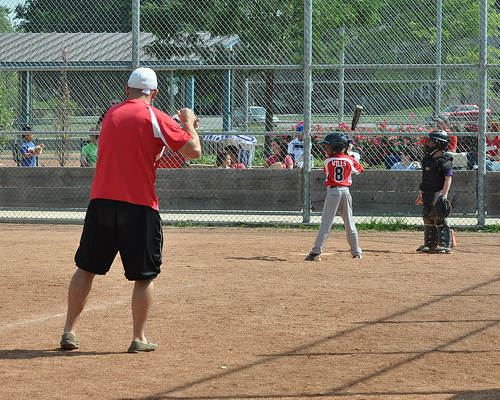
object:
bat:
[349, 105, 363, 138]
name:
[332, 160, 347, 166]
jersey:
[322, 153, 363, 186]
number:
[334, 166, 345, 182]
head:
[322, 133, 349, 157]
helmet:
[426, 130, 451, 149]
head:
[426, 130, 449, 150]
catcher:
[414, 129, 454, 254]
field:
[0, 216, 500, 400]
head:
[125, 67, 158, 102]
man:
[60, 66, 203, 352]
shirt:
[323, 153, 363, 186]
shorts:
[73, 198, 163, 281]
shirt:
[88, 98, 192, 212]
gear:
[423, 135, 439, 241]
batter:
[304, 132, 363, 261]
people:
[250, 128, 493, 164]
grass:
[287, 116, 423, 121]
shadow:
[0, 347, 126, 358]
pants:
[309, 187, 362, 257]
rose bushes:
[315, 120, 436, 144]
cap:
[127, 67, 158, 89]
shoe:
[127, 339, 158, 355]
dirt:
[198, 236, 495, 380]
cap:
[318, 132, 348, 154]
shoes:
[59, 332, 80, 350]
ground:
[0, 228, 498, 400]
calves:
[131, 280, 154, 339]